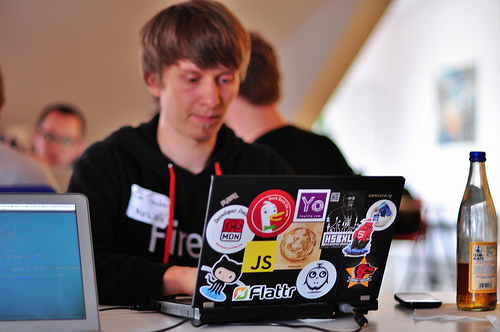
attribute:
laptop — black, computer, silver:
[210, 176, 380, 322]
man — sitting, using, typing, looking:
[101, 8, 231, 283]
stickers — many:
[221, 201, 305, 270]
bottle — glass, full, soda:
[449, 161, 491, 312]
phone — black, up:
[399, 293, 432, 306]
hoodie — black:
[97, 232, 144, 260]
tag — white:
[127, 186, 167, 225]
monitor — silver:
[0, 190, 96, 329]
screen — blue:
[218, 179, 386, 299]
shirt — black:
[169, 179, 203, 195]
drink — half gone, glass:
[461, 179, 483, 257]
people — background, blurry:
[186, 62, 279, 164]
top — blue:
[466, 152, 485, 164]